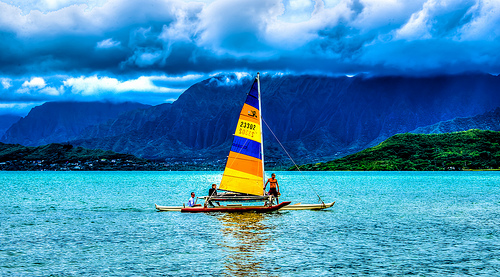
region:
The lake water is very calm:
[62, 216, 450, 271]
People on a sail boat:
[148, 70, 350, 225]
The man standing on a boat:
[258, 170, 283, 206]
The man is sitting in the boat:
[181, 181, 207, 213]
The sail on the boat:
[221, 79, 269, 196]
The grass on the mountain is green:
[352, 135, 495, 172]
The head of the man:
[263, 168, 280, 178]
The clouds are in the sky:
[37, 8, 267, 42]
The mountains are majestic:
[73, 70, 446, 144]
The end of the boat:
[253, 197, 293, 215]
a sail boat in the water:
[149, 66, 349, 218]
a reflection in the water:
[219, 216, 283, 274]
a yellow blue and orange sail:
[219, 76, 268, 196]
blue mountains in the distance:
[7, 73, 491, 155]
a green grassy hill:
[333, 131, 497, 170]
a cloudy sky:
[0, 2, 492, 84]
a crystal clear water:
[32, 178, 141, 245]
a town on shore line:
[35, 158, 185, 172]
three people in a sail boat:
[157, 75, 296, 215]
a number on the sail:
[232, 106, 269, 138]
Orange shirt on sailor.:
[267, 178, 279, 188]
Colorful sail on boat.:
[220, 79, 267, 204]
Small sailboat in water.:
[157, 200, 288, 214]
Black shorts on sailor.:
[268, 185, 279, 196]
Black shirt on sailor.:
[208, 189, 217, 198]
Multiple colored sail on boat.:
[220, 79, 267, 199]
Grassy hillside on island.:
[307, 128, 499, 169]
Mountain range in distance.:
[68, 72, 498, 159]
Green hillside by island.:
[323, 128, 498, 177]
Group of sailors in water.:
[157, 70, 335, 214]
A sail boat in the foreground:
[150, 70, 341, 225]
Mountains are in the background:
[1, 46, 497, 164]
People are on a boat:
[176, 165, 287, 216]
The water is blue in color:
[1, 173, 496, 273]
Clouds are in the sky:
[2, 2, 497, 99]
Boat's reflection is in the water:
[202, 205, 268, 273]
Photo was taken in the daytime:
[3, 1, 495, 273]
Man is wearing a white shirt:
[178, 186, 206, 206]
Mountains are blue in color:
[2, 70, 495, 170]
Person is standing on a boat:
[258, 169, 285, 211]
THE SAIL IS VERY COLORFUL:
[210, 60, 272, 201]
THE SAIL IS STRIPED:
[202, 68, 277, 206]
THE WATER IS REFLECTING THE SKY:
[0, 163, 496, 273]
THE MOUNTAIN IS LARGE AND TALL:
[20, 65, 491, 170]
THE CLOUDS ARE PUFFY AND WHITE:
[1, 3, 491, 129]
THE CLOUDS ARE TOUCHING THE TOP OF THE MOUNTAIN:
[1, 0, 496, 110]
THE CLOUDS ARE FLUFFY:
[0, 0, 493, 97]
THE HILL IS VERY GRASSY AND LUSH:
[297, 117, 497, 182]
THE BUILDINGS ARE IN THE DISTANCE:
[0, 150, 336, 173]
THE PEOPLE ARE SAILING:
[183, 175, 300, 217]